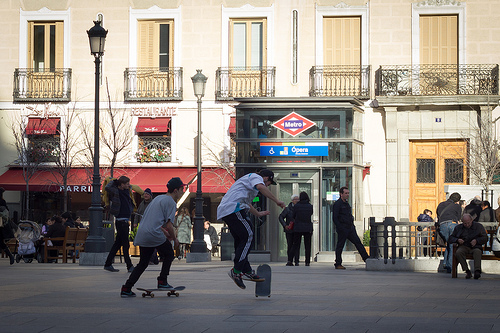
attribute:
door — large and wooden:
[280, 170, 317, 188]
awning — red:
[2, 161, 242, 195]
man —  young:
[121, 177, 183, 292]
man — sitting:
[452, 211, 488, 282]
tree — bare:
[451, 111, 495, 179]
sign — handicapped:
[257, 138, 331, 160]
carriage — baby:
[15, 219, 46, 259]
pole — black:
[90, 57, 100, 252]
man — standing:
[330, 185, 372, 269]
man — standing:
[115, 174, 184, 299]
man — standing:
[100, 172, 137, 272]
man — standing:
[215, 172, 286, 287]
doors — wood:
[408, 138, 473, 255]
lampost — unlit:
[75, 22, 125, 89]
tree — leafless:
[444, 83, 498, 198]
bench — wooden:
[45, 224, 83, 262]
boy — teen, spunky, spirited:
[119, 174, 197, 300]